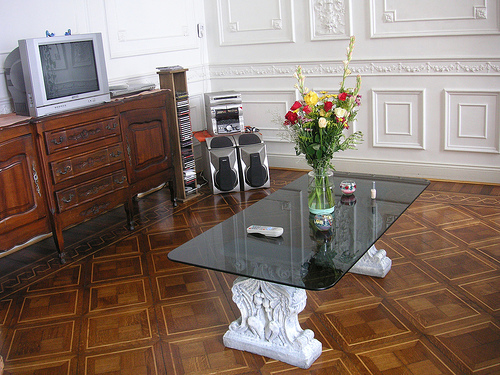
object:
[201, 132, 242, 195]
speaker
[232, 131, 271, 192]
speaker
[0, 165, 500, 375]
floor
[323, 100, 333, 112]
rose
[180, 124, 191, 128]
cds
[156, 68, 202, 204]
shelf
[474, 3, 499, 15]
walls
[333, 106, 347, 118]
flowers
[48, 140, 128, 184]
drawers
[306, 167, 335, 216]
glass vase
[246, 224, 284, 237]
remote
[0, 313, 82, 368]
tile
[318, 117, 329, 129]
flowers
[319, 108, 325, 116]
flowers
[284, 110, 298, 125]
flowers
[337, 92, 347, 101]
flowers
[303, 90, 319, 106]
flowers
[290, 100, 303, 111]
flowers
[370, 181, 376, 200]
nail polish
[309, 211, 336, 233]
pot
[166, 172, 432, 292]
glass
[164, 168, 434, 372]
table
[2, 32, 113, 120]
tv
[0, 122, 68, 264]
cabinet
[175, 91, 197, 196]
stack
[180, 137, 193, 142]
cds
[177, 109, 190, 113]
cds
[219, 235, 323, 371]
leg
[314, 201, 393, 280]
leg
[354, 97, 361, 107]
flowers